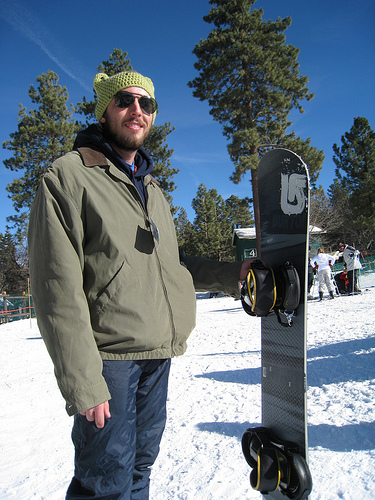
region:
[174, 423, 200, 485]
the snow is white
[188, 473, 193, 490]
the snow is white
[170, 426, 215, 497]
the snow is white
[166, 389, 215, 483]
the snow is white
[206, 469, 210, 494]
the snow is white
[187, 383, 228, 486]
the snow is white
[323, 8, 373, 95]
The sky is blue.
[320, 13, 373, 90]
The sky is clear.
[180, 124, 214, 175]
Thin clouds are in the sky.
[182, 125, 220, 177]
The clouds are white.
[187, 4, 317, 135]
Trees are in the background.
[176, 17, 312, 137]
The trees have leaves.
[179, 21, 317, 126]
The trees are green.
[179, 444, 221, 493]
Snow is on the ground.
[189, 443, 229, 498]
The snow is white.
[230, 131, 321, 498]
A snowboard.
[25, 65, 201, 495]
the man standing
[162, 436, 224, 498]
the snow on the ground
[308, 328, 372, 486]
the shadow on the snow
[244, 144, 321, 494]
the snow board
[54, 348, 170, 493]
the man's blue pants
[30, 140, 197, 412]
the man's green jacket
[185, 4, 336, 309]
the tall green tree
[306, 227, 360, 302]
the people standing in the back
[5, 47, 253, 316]
the group of trees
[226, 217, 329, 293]
the small building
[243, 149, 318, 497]
black snowboard with white logo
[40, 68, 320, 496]
man holding black snowboard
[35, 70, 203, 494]
man wearing blue pants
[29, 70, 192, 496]
man wearing green jacket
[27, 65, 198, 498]
man wearing blue sweatshirt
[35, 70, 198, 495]
man wearing green hat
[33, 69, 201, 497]
man wearing dark glasses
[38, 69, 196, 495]
man has dark beard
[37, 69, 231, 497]
man standing on snow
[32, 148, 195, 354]
ski tag attached to jacket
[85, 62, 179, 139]
Man wearing a green beanie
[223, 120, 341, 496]
Snowboard is standing on its end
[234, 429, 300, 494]
The snowboard has foot holders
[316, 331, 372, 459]
Shadow on the snow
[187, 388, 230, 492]
Tracks in the snow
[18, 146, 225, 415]
Man wearing a winter coat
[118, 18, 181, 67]
The sky is a vibrant blue color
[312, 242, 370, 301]
Two skiers standing in the background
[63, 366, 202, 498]
The man is wearing waterproof pants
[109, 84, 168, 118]
Man is wearing sunglasses